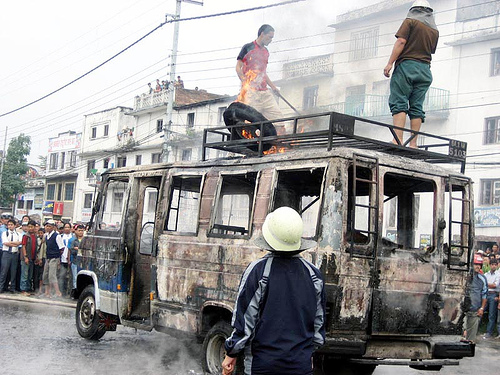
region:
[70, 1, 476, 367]
men standing on top of burnt truck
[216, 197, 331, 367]
man standing in back of windowless truck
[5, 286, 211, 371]
black paved street covered with light smoke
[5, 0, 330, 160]
bright sky behind poles and electrical wires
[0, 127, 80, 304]
crowd on curb in front of trees and buildings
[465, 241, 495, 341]
man standing in front of others looking sideways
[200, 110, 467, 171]
black railing and platform on top of truck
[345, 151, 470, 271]
ladders on either side of back of truck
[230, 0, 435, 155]
gray smoke between two men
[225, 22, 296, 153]
orange fire and black tire in front of man with stick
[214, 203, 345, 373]
person wearing hard hat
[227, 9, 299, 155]
person wearing a red shirt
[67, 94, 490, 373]
a burning van on street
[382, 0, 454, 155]
person wearing green pants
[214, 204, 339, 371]
person wearing blue jacket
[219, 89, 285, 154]
burning tire on roof of car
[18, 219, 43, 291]
person wearing a vest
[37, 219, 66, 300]
person wearing a hat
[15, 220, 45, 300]
person wearing blue jeans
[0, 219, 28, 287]
person wearing a shirt and tie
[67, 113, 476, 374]
a burned out bus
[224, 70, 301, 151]
a tire on fire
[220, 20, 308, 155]
a man starting a fire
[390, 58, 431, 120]
a pair of blue rolled up pants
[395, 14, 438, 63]
a brown t-shirt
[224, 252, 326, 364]
a blue and white jacket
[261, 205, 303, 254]
a white protective hemlet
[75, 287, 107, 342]
a bus front tire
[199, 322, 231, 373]
a bus rear tire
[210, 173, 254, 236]
a broken out bus window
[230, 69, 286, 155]
flame on top of a vehicle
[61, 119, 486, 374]
a burnt bus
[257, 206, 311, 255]
a white helmet on a man's head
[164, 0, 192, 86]
a utility pole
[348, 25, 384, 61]
bars in a window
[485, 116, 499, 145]
a window in a building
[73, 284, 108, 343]
a wheel on a bus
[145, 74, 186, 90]
people on top of a building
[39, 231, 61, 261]
a black vest on a man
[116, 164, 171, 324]
a door opening on a bus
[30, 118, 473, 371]
Burnt up van in street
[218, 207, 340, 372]
Person standing on pavement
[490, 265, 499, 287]
Person standing on pavement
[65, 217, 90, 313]
Person standing on pavement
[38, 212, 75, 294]
Person standing on pavement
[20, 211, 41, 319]
Person standing on pavement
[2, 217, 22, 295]
Person standing on pavement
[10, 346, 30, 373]
Small part of pavement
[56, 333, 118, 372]
Small part of pavement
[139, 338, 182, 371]
Small part of pavement